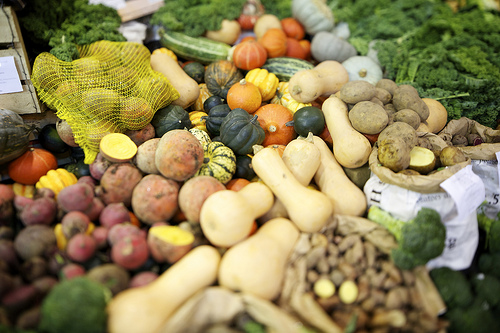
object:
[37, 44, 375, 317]
vegetables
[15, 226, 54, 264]
potatoes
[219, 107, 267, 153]
pumpkins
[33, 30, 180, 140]
potatoes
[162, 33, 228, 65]
zucchini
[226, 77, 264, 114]
oranges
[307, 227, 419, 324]
legumes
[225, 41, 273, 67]
goard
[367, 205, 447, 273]
broccoli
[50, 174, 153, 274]
veggies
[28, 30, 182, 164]
bag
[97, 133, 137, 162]
food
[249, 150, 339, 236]
squash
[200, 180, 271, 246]
squash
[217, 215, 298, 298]
squash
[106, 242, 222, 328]
squash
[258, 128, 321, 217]
squash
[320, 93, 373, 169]
squash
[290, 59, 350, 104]
squash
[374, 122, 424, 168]
potato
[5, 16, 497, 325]
table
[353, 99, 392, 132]
potato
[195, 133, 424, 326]
group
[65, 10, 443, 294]
view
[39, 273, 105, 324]
leafs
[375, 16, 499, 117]
veges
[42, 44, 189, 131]
nut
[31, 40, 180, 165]
apples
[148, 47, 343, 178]
pile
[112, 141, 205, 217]
pile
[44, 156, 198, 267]
pile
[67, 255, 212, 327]
pile